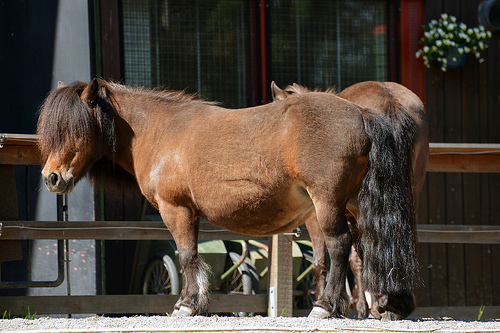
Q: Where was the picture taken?
A: Stable.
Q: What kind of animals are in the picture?
A: Horses.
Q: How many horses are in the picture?
A: Two.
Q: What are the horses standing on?
A: Dirt.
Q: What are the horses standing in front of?
A: Fence.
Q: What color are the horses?
A: Brown.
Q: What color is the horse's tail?
A: Black.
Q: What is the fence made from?
A: Wood.